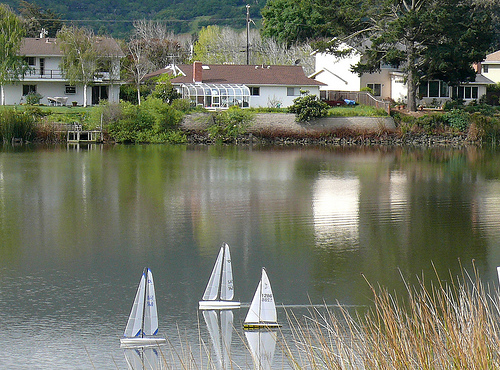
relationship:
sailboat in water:
[121, 265, 168, 347] [0, 143, 499, 368]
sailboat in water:
[199, 242, 241, 312] [0, 143, 499, 368]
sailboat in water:
[243, 266, 281, 330] [0, 143, 499, 368]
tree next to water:
[261, 0, 498, 114] [0, 143, 499, 368]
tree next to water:
[0, 0, 33, 106] [0, 143, 499, 368]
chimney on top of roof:
[192, 60, 203, 84] [134, 64, 330, 86]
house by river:
[130, 63, 323, 109] [0, 143, 499, 368]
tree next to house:
[116, 34, 168, 111] [130, 63, 323, 109]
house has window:
[130, 63, 323, 109] [241, 84, 260, 96]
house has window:
[130, 63, 323, 109] [285, 87, 300, 96]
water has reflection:
[0, 143, 499, 368] [308, 174, 362, 252]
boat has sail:
[121, 265, 168, 347] [122, 268, 161, 338]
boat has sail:
[199, 242, 241, 312] [200, 244, 235, 299]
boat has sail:
[243, 266, 281, 330] [241, 269, 279, 322]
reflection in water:
[308, 174, 362, 252] [0, 143, 499, 368]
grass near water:
[265, 257, 499, 370] [0, 143, 499, 368]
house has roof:
[130, 63, 323, 109] [134, 64, 330, 86]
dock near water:
[0, 115, 105, 145] [0, 143, 499, 368]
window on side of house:
[241, 84, 260, 96] [130, 63, 323, 109]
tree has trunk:
[261, 0, 498, 114] [404, 35, 418, 114]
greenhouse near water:
[172, 83, 250, 109] [0, 143, 499, 368]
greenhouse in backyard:
[172, 83, 250, 109] [185, 98, 387, 131]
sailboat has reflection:
[199, 242, 241, 312] [200, 312, 237, 370]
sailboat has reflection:
[243, 266, 281, 330] [244, 330, 279, 370]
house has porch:
[130, 63, 323, 109] [172, 83, 250, 109]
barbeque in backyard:
[45, 94, 68, 107] [0, 105, 151, 134]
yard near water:
[0, 105, 151, 134] [0, 143, 499, 368]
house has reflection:
[130, 63, 323, 109] [308, 174, 362, 252]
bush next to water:
[107, 94, 187, 144] [0, 143, 499, 368]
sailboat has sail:
[121, 265, 168, 347] [122, 268, 161, 338]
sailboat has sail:
[199, 242, 241, 312] [200, 244, 235, 299]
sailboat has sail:
[243, 266, 281, 330] [241, 269, 279, 322]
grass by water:
[265, 257, 499, 370] [0, 143, 499, 368]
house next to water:
[130, 63, 323, 109] [0, 143, 499, 368]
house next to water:
[0, 33, 127, 103] [0, 143, 499, 368]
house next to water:
[310, 27, 495, 108] [0, 143, 499, 368]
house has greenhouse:
[130, 63, 323, 109] [172, 83, 250, 109]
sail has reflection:
[122, 268, 161, 338] [121, 350, 161, 369]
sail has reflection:
[200, 244, 235, 299] [200, 312, 237, 370]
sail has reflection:
[241, 269, 279, 322] [244, 330, 279, 370]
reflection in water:
[121, 350, 161, 369] [0, 143, 499, 368]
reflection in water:
[200, 312, 237, 370] [0, 143, 499, 368]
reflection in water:
[244, 330, 279, 370] [0, 143, 499, 368]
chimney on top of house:
[192, 60, 203, 84] [130, 63, 323, 109]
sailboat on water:
[121, 265, 168, 347] [0, 143, 499, 368]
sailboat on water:
[199, 242, 241, 312] [0, 143, 499, 368]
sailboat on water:
[243, 266, 281, 330] [0, 143, 499, 368]